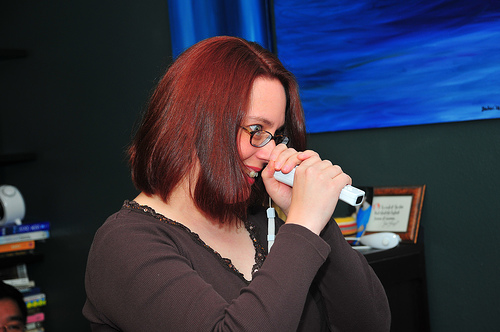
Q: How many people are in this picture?
A: One.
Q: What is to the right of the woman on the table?
A: A Plaque.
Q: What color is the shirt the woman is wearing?
A: Brown.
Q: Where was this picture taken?
A: In class.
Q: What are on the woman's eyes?
A: Glasses.